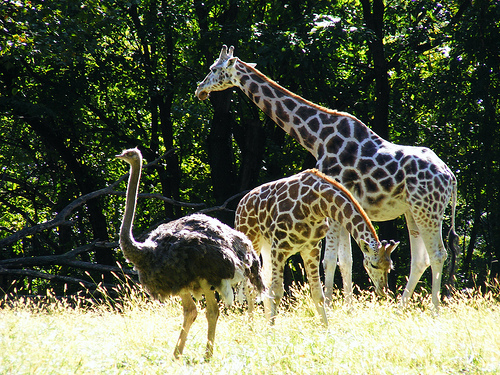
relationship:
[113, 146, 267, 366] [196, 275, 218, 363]
ostrich has a leg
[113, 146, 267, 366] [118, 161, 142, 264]
ostrich has a neck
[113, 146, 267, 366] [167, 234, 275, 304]
ostrich has feathers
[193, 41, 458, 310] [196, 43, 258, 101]
giraffe has a head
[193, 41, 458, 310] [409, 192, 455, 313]
giraffe has a back leg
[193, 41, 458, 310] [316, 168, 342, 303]
giraffe has a front leg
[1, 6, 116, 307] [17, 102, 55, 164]
tree has a branch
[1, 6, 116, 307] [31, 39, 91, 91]
tree has leaves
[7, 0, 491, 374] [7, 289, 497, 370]
plantation has grass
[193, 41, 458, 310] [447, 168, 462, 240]
giraffe has a tail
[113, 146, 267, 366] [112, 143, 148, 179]
ostrich has a head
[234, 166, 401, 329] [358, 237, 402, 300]
animal has a head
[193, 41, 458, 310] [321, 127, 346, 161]
giraffe has a spot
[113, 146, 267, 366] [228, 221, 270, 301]
ostrich has a tail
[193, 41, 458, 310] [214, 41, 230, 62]
giraffe has an ear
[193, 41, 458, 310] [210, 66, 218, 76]
giraffe has an eye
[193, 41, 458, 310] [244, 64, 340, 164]
giraffe has a neck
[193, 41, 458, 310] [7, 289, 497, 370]
animal in a field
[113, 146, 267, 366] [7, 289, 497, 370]
animal in a field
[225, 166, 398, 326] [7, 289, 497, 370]
animal in a field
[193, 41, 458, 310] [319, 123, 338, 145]
giraffe has spots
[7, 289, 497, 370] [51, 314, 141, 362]
grass has a patch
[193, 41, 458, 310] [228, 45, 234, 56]
giraffe has right ear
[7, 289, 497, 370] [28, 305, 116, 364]
grass has a part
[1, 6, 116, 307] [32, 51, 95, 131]
tree has branches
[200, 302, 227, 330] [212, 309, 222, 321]
knee has a part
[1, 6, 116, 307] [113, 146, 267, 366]
trees behind ostrich